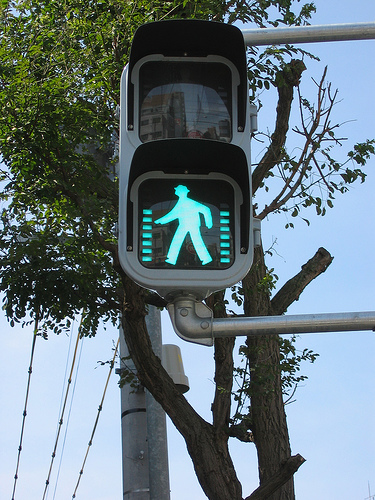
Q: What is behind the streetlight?
A: A tree.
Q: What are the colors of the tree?
A: It's brown and green.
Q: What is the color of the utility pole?
A: It's gray.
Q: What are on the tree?
A: It's leaves.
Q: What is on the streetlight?
A: A walking man.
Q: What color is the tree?
A: Green.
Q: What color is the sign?
A: Black.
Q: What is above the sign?
A: Power lines.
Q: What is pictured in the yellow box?
A: A traffic light.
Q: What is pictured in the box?
A: A lighted walking sign.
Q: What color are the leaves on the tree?
A: Green.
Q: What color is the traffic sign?
A: Black.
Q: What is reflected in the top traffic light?
A: The city.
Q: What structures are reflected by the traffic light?
A: Several buildings.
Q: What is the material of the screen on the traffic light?
A: Glass.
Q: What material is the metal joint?
A: Metal.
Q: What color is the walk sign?
A: Green.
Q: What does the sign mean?
A: People can walk.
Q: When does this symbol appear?
A: When it is safe to cross.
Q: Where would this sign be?
A: At a crosswalk.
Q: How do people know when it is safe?
A: The image and color change.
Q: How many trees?
A: One.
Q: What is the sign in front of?
A: A tree.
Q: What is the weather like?
A: Sunny.